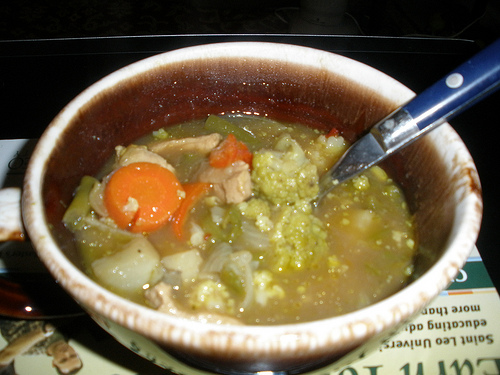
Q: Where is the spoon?
A: The bowl.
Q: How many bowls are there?
A: One.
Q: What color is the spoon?
A: Blue.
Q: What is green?
A: The veggies.